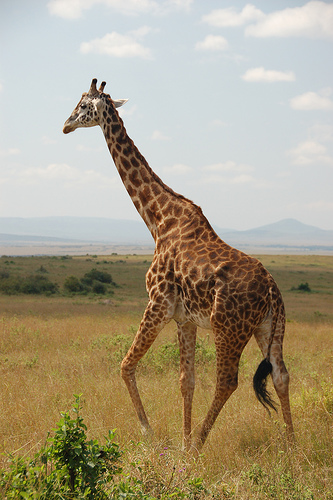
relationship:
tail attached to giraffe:
[254, 290, 281, 416] [65, 78, 299, 453]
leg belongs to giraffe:
[194, 302, 242, 461] [65, 78, 299, 453]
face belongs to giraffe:
[62, 88, 103, 140] [65, 78, 299, 453]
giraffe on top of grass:
[65, 78, 299, 453] [233, 440, 265, 483]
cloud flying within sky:
[243, 63, 295, 87] [132, 4, 332, 142]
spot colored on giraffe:
[135, 185, 154, 207] [65, 78, 299, 453]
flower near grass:
[22, 475, 27, 484] [233, 440, 265, 483]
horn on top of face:
[90, 76, 100, 92] [62, 88, 103, 140]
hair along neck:
[108, 96, 132, 142] [99, 125, 180, 233]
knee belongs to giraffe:
[121, 357, 139, 382] [65, 78, 299, 453]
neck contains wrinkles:
[99, 125, 180, 233] [152, 220, 184, 234]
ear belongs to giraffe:
[112, 98, 129, 108] [65, 78, 299, 453]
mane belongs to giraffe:
[112, 112, 173, 201] [65, 78, 299, 453]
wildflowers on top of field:
[16, 427, 157, 500] [1, 244, 125, 492]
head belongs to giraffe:
[57, 79, 128, 137] [65, 78, 299, 453]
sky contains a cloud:
[132, 4, 332, 142] [243, 63, 295, 87]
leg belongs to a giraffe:
[194, 302, 242, 461] [65, 78, 299, 453]